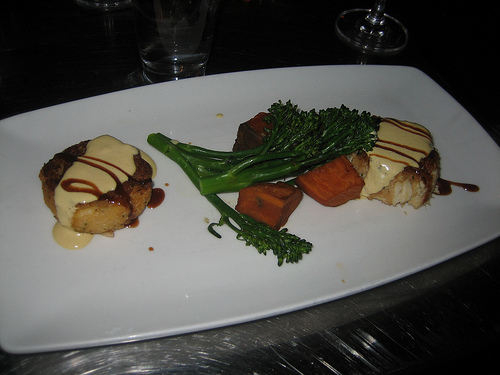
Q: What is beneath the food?
A: A plate.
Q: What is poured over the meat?
A: Sauce.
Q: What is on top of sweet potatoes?
A: Broccoli.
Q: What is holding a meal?
A: A large white plate.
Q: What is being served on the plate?
A: A meal.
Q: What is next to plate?
A: Empty glass.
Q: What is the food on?
A: Plate.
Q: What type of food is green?
A: Broccoli.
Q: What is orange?
A: Carrots.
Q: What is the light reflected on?
A: Table.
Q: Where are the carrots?
A: Under the broccoli.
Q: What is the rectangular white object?
A: Plate.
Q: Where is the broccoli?
A: Middle of the plate.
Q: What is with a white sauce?
A: The meat.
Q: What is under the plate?
A: Black table.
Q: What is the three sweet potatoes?
A: Roasted.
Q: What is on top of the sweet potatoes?
A: Green broccoli.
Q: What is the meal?
A: On the plate.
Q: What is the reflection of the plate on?
A: The table.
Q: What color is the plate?
A: White.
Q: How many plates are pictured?
A: One.